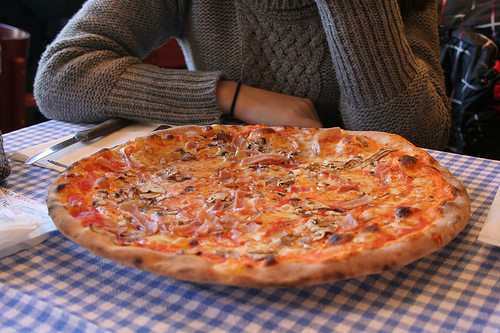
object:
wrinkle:
[0, 281, 111, 332]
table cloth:
[0, 119, 499, 332]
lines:
[193, 287, 263, 332]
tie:
[228, 82, 243, 120]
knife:
[22, 117, 130, 166]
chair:
[0, 23, 32, 134]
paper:
[13, 122, 178, 172]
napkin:
[476, 186, 499, 246]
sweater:
[33, 0, 451, 150]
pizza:
[45, 124, 470, 287]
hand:
[231, 80, 323, 128]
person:
[33, 0, 451, 151]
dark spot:
[65, 173, 77, 177]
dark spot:
[266, 256, 278, 266]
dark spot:
[194, 249, 204, 256]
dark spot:
[394, 205, 410, 217]